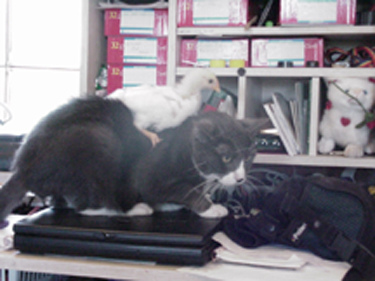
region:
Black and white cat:
[0, 93, 261, 217]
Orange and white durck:
[109, 67, 220, 151]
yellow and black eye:
[220, 152, 232, 163]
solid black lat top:
[12, 206, 217, 265]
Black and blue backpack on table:
[242, 172, 372, 274]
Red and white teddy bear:
[316, 73, 373, 156]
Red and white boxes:
[181, 40, 247, 64]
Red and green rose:
[327, 78, 372, 129]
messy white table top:
[0, 214, 343, 278]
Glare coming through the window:
[0, 0, 81, 136]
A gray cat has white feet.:
[1, 98, 267, 220]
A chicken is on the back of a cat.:
[1, 65, 264, 219]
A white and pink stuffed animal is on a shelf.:
[319, 77, 374, 166]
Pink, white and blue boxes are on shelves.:
[97, 0, 358, 95]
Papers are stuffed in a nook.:
[260, 76, 306, 153]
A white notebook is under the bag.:
[209, 170, 369, 269]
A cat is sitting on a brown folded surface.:
[13, 96, 271, 262]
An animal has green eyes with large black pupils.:
[220, 150, 253, 167]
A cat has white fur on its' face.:
[201, 151, 255, 189]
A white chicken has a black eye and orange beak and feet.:
[104, 49, 220, 145]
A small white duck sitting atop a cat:
[97, 62, 223, 145]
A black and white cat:
[9, 95, 266, 226]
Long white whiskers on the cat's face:
[186, 164, 282, 199]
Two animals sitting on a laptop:
[11, 64, 275, 231]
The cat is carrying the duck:
[4, 64, 271, 229]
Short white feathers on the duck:
[134, 87, 191, 114]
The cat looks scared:
[194, 114, 260, 194]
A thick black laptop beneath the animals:
[10, 205, 239, 262]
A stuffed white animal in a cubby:
[313, 75, 373, 166]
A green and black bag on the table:
[288, 171, 368, 258]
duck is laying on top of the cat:
[96, 60, 225, 135]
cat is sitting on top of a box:
[12, 95, 249, 211]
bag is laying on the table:
[242, 168, 362, 265]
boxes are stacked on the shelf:
[98, 10, 168, 85]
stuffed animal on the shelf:
[319, 83, 372, 160]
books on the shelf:
[259, 71, 313, 154]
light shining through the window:
[8, 10, 57, 103]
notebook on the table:
[212, 238, 284, 279]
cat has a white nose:
[206, 166, 252, 187]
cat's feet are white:
[87, 198, 232, 239]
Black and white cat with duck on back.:
[2, 56, 270, 230]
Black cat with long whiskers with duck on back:
[1, 68, 263, 227]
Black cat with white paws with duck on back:
[1, 68, 247, 237]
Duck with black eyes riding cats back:
[0, 65, 284, 238]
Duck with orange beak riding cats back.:
[0, 70, 265, 262]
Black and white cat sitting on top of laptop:
[0, 64, 276, 267]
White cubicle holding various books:
[83, 0, 373, 167]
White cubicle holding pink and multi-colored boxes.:
[82, 2, 373, 171]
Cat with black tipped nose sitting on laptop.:
[0, 68, 273, 235]